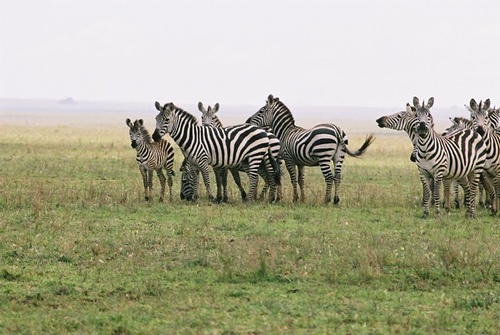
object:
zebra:
[151, 100, 283, 206]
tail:
[337, 131, 377, 158]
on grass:
[0, 124, 497, 333]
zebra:
[179, 158, 199, 202]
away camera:
[248, 331, 251, 335]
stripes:
[228, 126, 262, 167]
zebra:
[375, 102, 417, 147]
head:
[375, 102, 413, 132]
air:
[0, 0, 500, 131]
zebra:
[468, 97, 500, 217]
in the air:
[0, 0, 500, 335]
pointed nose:
[375, 115, 389, 128]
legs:
[418, 172, 432, 220]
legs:
[333, 160, 345, 204]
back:
[284, 125, 314, 140]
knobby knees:
[143, 181, 149, 187]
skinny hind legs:
[166, 166, 175, 201]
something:
[57, 96, 78, 106]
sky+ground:
[0, 0, 500, 335]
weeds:
[78, 186, 87, 201]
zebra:
[443, 115, 500, 216]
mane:
[453, 116, 476, 130]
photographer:
[231, 328, 239, 335]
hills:
[0, 93, 500, 124]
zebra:
[412, 95, 490, 223]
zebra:
[124, 118, 177, 204]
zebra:
[198, 101, 285, 204]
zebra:
[244, 93, 378, 207]